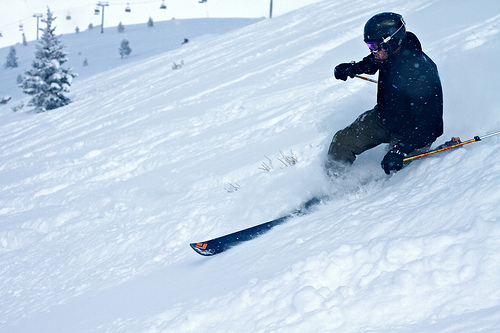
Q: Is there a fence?
A: No, there are no fences.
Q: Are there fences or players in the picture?
A: No, there are no fences or players.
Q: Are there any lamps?
A: No, there are no lamps.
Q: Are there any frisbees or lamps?
A: No, there are no lamps or frisbees.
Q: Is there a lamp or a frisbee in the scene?
A: No, there are no lamps or frisbees.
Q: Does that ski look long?
A: Yes, the ski is long.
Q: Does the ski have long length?
A: Yes, the ski is long.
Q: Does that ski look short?
A: No, the ski is long.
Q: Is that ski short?
A: No, the ski is long.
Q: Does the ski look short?
A: No, the ski is long.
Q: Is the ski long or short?
A: The ski is long.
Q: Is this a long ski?
A: Yes, this is a long ski.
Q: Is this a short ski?
A: No, this is a long ski.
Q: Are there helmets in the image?
A: Yes, there is a helmet.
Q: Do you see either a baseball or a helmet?
A: Yes, there is a helmet.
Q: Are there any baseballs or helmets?
A: Yes, there is a helmet.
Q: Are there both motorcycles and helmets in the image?
A: No, there is a helmet but no motorcycles.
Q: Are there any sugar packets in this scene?
A: No, there are no sugar packets.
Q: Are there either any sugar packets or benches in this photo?
A: No, there are no sugar packets or benches.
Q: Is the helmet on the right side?
A: Yes, the helmet is on the right of the image.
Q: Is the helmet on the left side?
A: No, the helmet is on the right of the image.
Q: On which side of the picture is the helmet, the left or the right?
A: The helmet is on the right of the image.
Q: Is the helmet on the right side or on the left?
A: The helmet is on the right of the image.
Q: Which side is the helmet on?
A: The helmet is on the right of the image.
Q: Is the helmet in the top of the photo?
A: Yes, the helmet is in the top of the image.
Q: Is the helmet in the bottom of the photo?
A: No, the helmet is in the top of the image.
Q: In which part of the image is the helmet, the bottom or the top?
A: The helmet is in the top of the image.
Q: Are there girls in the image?
A: No, there are no girls.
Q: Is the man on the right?
A: Yes, the man is on the right of the image.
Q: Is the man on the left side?
A: No, the man is on the right of the image.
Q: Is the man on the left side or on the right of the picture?
A: The man is on the right of the image.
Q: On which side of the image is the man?
A: The man is on the right of the image.